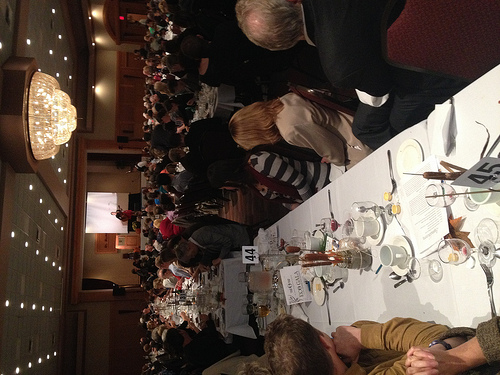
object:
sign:
[451, 157, 499, 189]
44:
[245, 248, 256, 261]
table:
[238, 65, 500, 335]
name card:
[278, 265, 312, 305]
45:
[467, 161, 500, 185]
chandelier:
[26, 71, 82, 162]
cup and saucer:
[378, 235, 412, 276]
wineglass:
[320, 217, 355, 234]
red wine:
[331, 220, 339, 231]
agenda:
[395, 154, 450, 257]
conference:
[72, 9, 496, 374]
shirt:
[248, 150, 326, 207]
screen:
[88, 192, 129, 233]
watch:
[428, 339, 453, 350]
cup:
[355, 216, 378, 238]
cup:
[306, 237, 323, 250]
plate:
[395, 139, 424, 180]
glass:
[438, 239, 497, 266]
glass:
[409, 258, 442, 281]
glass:
[426, 182, 498, 209]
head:
[264, 314, 336, 373]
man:
[260, 313, 448, 375]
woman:
[229, 92, 371, 173]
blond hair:
[228, 99, 284, 150]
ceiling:
[3, 5, 84, 257]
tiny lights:
[39, 0, 78, 92]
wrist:
[446, 341, 478, 373]